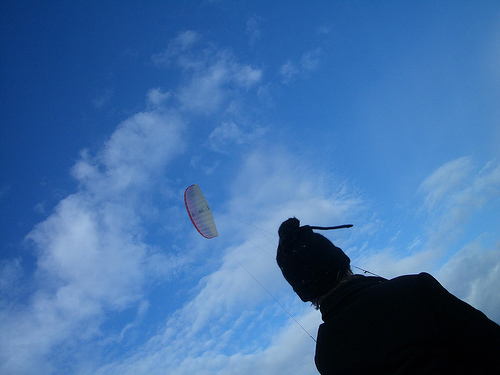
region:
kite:
[168, 174, 223, 247]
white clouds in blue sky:
[314, 99, 393, 144]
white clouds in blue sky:
[131, 300, 186, 325]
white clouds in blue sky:
[131, 275, 161, 303]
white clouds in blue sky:
[42, 187, 137, 242]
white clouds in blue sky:
[270, 28, 322, 99]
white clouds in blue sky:
[21, 83, 89, 134]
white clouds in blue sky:
[137, 288, 199, 335]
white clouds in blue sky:
[94, 85, 159, 125]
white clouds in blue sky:
[25, 193, 95, 285]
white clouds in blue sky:
[371, 119, 433, 154]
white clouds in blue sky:
[68, 305, 105, 319]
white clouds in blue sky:
[172, 283, 200, 301]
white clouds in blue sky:
[4, 175, 85, 227]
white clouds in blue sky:
[367, 46, 421, 98]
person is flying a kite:
[158, 165, 358, 351]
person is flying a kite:
[162, 164, 359, 342]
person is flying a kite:
[139, 148, 343, 373]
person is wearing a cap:
[260, 210, 352, 298]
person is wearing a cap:
[263, 205, 334, 317]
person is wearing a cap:
[266, 201, 376, 322]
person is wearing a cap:
[248, 202, 348, 312]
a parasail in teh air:
[144, 143, 281, 266]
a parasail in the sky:
[169, 155, 258, 286]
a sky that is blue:
[86, 6, 492, 296]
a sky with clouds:
[91, 8, 406, 263]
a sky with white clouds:
[69, 51, 339, 189]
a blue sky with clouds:
[78, 36, 363, 266]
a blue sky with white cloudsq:
[104, 23, 418, 265]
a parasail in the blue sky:
[210, 115, 442, 359]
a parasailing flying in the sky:
[154, 140, 361, 294]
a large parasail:
[125, 107, 299, 284]